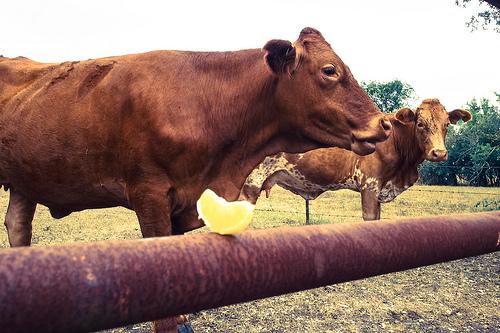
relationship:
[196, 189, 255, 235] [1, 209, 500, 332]
orange slice on pole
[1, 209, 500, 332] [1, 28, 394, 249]
pole in front of cow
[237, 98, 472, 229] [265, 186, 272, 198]
cow has a nipple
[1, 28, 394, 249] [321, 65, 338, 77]
cow has an eye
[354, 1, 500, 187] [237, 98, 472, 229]
trees behind cow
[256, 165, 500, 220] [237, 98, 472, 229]
barbed wire next to cow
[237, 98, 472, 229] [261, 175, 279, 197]
cow has udders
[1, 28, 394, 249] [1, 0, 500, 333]
cow in field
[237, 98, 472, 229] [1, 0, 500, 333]
cow in field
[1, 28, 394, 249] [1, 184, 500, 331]
cow on grass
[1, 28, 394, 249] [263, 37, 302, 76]
cow has an ear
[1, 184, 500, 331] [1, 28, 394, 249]
grass under cow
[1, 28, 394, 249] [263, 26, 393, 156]
cow has a head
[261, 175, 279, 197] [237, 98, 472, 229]
udders under cow